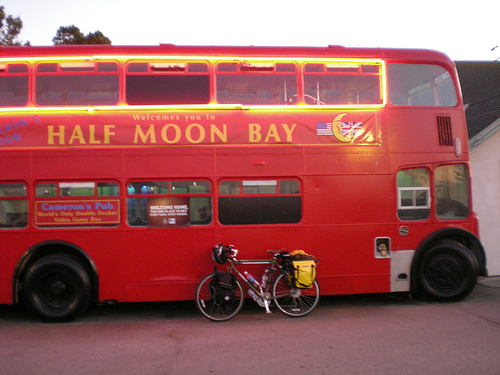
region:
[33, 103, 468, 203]
Words on the bus.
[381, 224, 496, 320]
Wheel on the bus.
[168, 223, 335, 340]
Bike by the bus.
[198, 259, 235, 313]
Wheel on the bike.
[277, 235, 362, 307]
Bag on the bike.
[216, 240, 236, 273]
Helmet on the bike.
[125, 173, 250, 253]
Window on the bus.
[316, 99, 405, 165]
moon on the bus.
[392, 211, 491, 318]
Black wheel on the red bus.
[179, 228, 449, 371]
Bike against the bus.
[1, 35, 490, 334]
red bus on pavement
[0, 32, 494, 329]
red double decker bus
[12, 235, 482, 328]
two black tires on side of bus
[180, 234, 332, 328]
bicycle leaning on side of bus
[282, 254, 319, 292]
yellow bag on back of bicycle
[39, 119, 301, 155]
name of bus carrier on side of bus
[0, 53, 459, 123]
windows on side of bus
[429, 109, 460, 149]
black grill on side of bus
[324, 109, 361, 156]
half moon on side of bus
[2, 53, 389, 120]
yellow digital neon light framing window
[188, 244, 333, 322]
Bicycle propped against bus.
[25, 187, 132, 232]
Ad for pub on the bus.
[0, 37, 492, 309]
Red double decker tour bus.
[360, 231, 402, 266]
Gas filling spot on bus.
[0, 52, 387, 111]
Neon lights on the bus.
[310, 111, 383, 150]
American and UK flag on bus.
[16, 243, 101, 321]
Shiny tires on the bus.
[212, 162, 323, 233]
Open window on the bus.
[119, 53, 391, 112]
One window opened, while two others are closed.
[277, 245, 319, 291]
Yellow bike bag.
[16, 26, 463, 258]
double deck red an dyellow bus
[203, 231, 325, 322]
bike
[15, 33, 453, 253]
yellow an red bus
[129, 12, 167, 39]
white clouds in blue sky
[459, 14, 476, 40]
white clouds in blue sky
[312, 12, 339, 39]
white clouds in blue sky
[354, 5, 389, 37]
white clouds in blue sky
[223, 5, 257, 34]
white clouds in blue sky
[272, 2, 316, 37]
white clouds in blue sky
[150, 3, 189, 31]
white clouds in blue sky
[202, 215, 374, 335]
a bike in front of bus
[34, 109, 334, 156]
half moon bay written on bus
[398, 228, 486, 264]
fender of the bus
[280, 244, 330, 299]
a yellow bag on bike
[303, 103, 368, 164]
us flag and moon with english flag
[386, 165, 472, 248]
window on the bus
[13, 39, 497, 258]
red and yellow bus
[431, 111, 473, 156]
vent on bus front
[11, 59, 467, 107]
windows across the top of bus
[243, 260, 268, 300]
water bottle on the bike